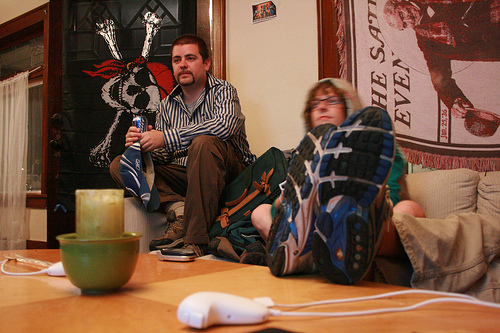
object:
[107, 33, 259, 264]
man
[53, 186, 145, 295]
bowl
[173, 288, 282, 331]
controller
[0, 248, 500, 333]
table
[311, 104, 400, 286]
sneakers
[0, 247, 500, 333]
surface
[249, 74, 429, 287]
person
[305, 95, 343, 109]
glasses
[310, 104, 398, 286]
feet